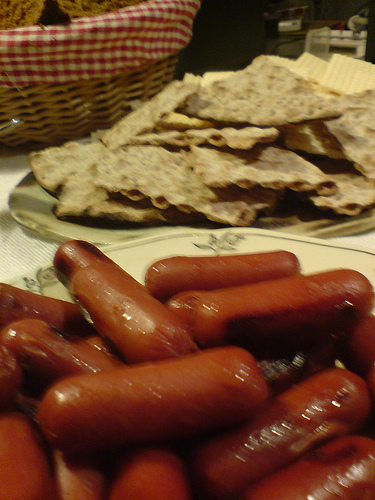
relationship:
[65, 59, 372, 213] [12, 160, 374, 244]
chips on platter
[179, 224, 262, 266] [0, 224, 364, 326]
flower on platter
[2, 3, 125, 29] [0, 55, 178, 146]
bread in basket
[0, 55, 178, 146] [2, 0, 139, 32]
basket with bread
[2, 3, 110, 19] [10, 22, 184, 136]
bread in basket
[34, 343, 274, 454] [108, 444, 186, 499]
sausage on top of sausage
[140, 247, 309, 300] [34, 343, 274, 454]
sausage on top of sausage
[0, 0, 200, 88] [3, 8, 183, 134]
cloth in basket.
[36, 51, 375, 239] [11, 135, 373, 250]
chips are on plate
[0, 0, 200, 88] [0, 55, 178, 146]
cloth in basket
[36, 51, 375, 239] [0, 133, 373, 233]
chips on plate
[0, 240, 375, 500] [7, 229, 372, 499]
hot dogs on plate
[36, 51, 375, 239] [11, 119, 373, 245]
chips are on plate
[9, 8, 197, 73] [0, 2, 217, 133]
cloth on basket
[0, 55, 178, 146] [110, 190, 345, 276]
basket next to plate